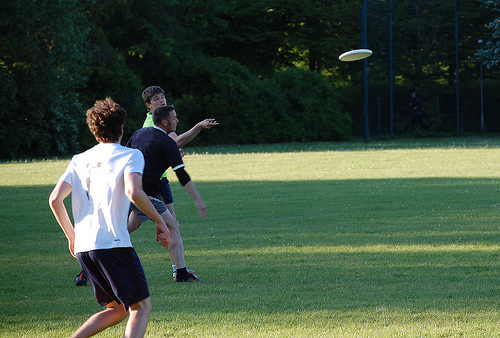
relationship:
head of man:
[85, 96, 129, 146] [45, 96, 175, 335]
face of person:
[150, 91, 167, 108] [139, 84, 221, 240]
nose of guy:
[175, 117, 178, 122] [125, 103, 208, 286]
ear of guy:
[158, 117, 170, 130] [125, 103, 208, 286]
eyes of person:
[153, 93, 165, 101] [139, 84, 221, 240]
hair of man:
[91, 115, 107, 128] [45, 96, 175, 335]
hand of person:
[194, 116, 225, 132] [139, 84, 221, 240]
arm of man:
[121, 175, 166, 224] [45, 96, 175, 335]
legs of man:
[65, 265, 160, 337] [45, 96, 175, 335]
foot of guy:
[174, 270, 201, 286] [125, 103, 208, 286]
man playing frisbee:
[45, 96, 175, 335] [333, 46, 378, 66]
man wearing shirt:
[45, 96, 175, 335] [56, 141, 149, 262]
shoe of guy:
[72, 269, 86, 287] [125, 103, 208, 286]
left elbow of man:
[44, 194, 67, 211] [45, 96, 175, 335]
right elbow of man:
[123, 184, 144, 205] [45, 96, 175, 335]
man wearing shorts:
[45, 96, 175, 335] [70, 248, 161, 315]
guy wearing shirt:
[125, 103, 208, 286] [129, 124, 185, 201]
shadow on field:
[3, 172, 498, 328] [6, 131, 496, 332]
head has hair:
[85, 96, 129, 146] [91, 115, 107, 128]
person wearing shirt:
[139, 84, 221, 240] [139, 110, 156, 127]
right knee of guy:
[171, 217, 184, 232] [125, 103, 208, 286]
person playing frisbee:
[139, 84, 221, 240] [333, 46, 378, 66]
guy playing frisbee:
[125, 103, 208, 286] [333, 46, 378, 66]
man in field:
[45, 96, 175, 335] [6, 131, 496, 332]